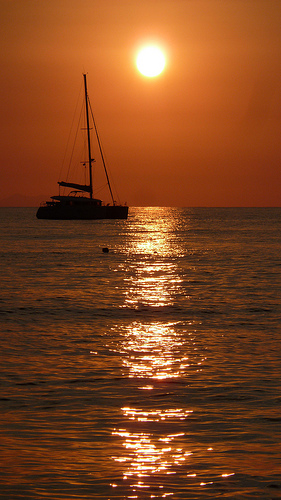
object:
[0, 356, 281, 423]
ripples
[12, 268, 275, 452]
water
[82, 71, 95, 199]
mast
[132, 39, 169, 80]
sun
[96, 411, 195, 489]
sun reflected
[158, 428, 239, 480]
water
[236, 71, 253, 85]
ground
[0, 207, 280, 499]
water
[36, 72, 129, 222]
boat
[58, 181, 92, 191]
sail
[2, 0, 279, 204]
sky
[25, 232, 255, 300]
water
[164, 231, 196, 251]
water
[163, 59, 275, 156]
sky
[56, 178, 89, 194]
sails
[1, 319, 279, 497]
sea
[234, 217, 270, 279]
water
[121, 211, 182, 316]
reflection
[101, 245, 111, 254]
object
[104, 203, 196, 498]
reflection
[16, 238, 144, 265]
water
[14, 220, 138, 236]
ocean